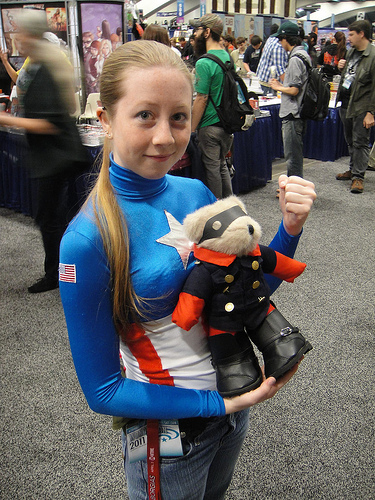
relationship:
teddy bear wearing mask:
[184, 193, 297, 375] [198, 204, 247, 244]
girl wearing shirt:
[59, 51, 228, 408] [72, 179, 291, 422]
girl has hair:
[59, 38, 317, 500] [86, 37, 194, 346]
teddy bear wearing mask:
[170, 193, 314, 399] [198, 204, 247, 244]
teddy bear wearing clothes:
[170, 193, 314, 399] [171, 242, 312, 398]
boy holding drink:
[269, 21, 309, 198] [266, 65, 280, 81]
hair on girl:
[87, 37, 191, 324] [59, 38, 317, 500]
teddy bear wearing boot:
[170, 193, 314, 399] [202, 329, 264, 398]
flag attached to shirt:
[56, 262, 77, 283] [55, 151, 304, 417]